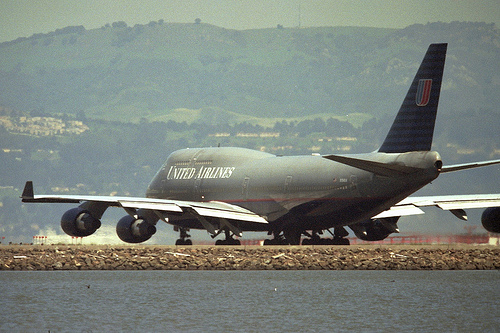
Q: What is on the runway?
A: United Airlines 747 on runway.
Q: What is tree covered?
A: Tree covered mountain in background.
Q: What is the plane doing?
A: Airplane ready for takeoff.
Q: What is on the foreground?
A: Body of water in the foreground.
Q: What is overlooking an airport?
A: Hills overlooking an airport.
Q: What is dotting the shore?
A: Many rocks.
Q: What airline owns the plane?
A: United Airlines.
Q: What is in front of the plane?
A: A mountain.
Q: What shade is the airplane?
A: Grey.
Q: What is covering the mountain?
A: Vegetation.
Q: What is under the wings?
A: The engines.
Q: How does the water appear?
A: Rippling.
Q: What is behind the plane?
A: A body of water.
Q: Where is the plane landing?
A: At the airport.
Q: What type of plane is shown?
A: A cargo plane.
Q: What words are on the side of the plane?
A: UNITED AIRLINES.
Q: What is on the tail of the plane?
A: An emblem.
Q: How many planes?
A: One.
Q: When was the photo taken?
A: Daytime.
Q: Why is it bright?
A: Sunny.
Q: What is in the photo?
A: A plane.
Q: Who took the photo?
A: A photographer.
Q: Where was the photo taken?
A: Airport.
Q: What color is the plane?
A: Grey.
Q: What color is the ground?
A: Brown.